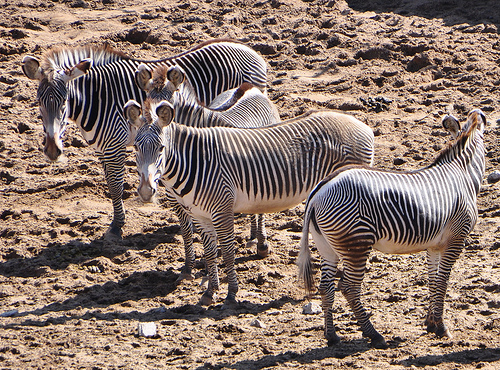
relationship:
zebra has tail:
[295, 101, 490, 343] [291, 200, 321, 292]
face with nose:
[101, 94, 190, 212] [127, 180, 159, 207]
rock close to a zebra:
[301, 291, 328, 323] [81, 92, 395, 324]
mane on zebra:
[38, 46, 117, 72] [20, 35, 270, 248]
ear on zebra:
[13, 46, 53, 84] [0, 35, 280, 247]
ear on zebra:
[65, 63, 96, 85] [0, 35, 280, 247]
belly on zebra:
[376, 236, 447, 258] [271, 115, 482, 351]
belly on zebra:
[231, 192, 315, 217] [118, 88, 381, 328]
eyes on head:
[124, 139, 176, 160] [101, 90, 188, 205]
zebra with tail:
[293, 109, 486, 351] [285, 196, 326, 300]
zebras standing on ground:
[7, 32, 481, 357] [10, 7, 474, 365]